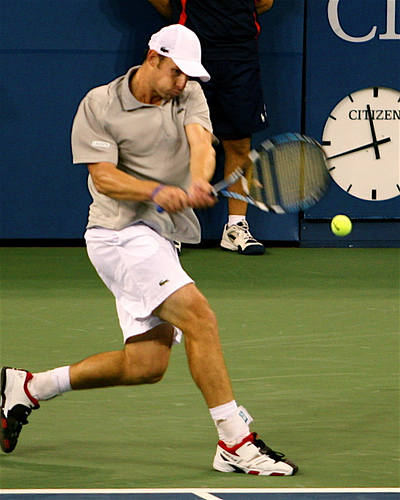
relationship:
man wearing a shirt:
[11, 16, 296, 483] [65, 58, 209, 242]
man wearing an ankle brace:
[11, 16, 296, 483] [213, 405, 254, 440]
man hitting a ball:
[0, 20, 299, 478] [320, 210, 359, 238]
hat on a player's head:
[148, 19, 214, 83] [139, 22, 202, 103]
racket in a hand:
[157, 132, 330, 214] [185, 179, 217, 207]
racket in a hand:
[157, 132, 330, 214] [150, 185, 187, 211]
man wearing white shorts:
[11, 16, 296, 483] [83, 226, 205, 342]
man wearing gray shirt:
[11, 16, 296, 483] [66, 62, 216, 247]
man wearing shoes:
[11, 16, 296, 483] [1, 353, 301, 483]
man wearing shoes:
[0, 20, 299, 478] [205, 426, 300, 478]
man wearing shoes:
[0, 20, 299, 478] [0, 362, 45, 454]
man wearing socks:
[11, 16, 296, 483] [208, 399, 253, 451]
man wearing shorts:
[0, 20, 299, 478] [63, 208, 204, 349]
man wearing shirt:
[0, 20, 299, 478] [68, 68, 218, 252]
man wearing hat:
[11, 16, 296, 483] [147, 25, 211, 80]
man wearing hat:
[11, 16, 296, 483] [137, 19, 239, 79]